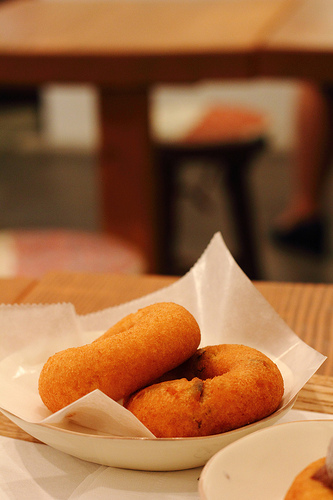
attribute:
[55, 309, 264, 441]
donuts — stacked, angled, plain, flat, golden, brown, yellow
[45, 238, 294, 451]
paper — triangular, white, thin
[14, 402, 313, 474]
plate — white, shallow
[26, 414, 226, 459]
edge — golden, gold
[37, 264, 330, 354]
table — woodgrain, light colored, brown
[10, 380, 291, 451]
saucer — white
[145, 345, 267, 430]
donut — dark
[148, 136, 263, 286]
stool — brown